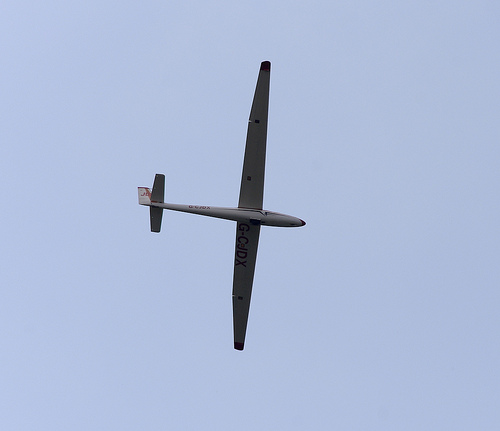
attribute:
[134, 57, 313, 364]
plane — gray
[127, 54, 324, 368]
plane — wider 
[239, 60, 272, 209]
wing — long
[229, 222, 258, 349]
wing — long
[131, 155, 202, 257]
wings — back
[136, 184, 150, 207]
stabilizer — vertical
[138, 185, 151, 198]
markings — red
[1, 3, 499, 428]
sky — clear, blue